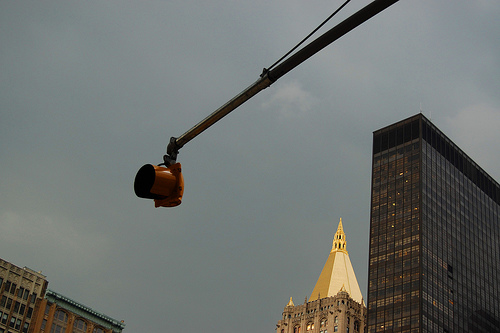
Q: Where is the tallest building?
A: To the right.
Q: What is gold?
A: The steeple.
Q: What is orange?
A: Light.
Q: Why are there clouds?
A: Weather.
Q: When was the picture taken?
A: Daytime.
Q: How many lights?
A: One.